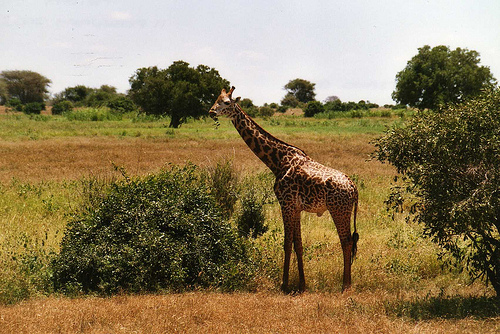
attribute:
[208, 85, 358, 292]
giraffe — tall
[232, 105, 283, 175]
neck — long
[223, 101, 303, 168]
neck — long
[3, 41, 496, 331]
giraffe field — lone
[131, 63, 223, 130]
tree — green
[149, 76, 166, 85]
leaf — green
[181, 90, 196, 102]
leaf — green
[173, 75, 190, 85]
leaf — green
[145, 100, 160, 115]
leaf — green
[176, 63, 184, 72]
leaf — green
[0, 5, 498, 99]
sky — cloudless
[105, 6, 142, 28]
cloud — solitary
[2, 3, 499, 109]
sky — distant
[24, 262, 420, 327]
grass — dead, brown